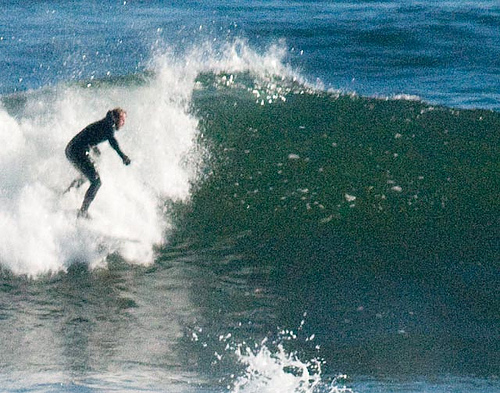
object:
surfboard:
[74, 225, 143, 243]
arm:
[105, 126, 125, 159]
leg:
[71, 151, 100, 186]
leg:
[65, 149, 102, 210]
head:
[111, 106, 127, 130]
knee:
[92, 180, 102, 186]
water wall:
[0, 92, 182, 247]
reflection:
[2, 263, 194, 392]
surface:
[0, 0, 499, 388]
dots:
[224, 76, 484, 222]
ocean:
[0, 0, 500, 393]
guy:
[62, 107, 131, 220]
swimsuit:
[62, 117, 128, 219]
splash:
[188, 311, 347, 393]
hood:
[106, 110, 119, 126]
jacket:
[69, 110, 126, 158]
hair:
[109, 106, 127, 122]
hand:
[123, 156, 131, 166]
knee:
[79, 173, 89, 180]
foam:
[0, 27, 459, 393]